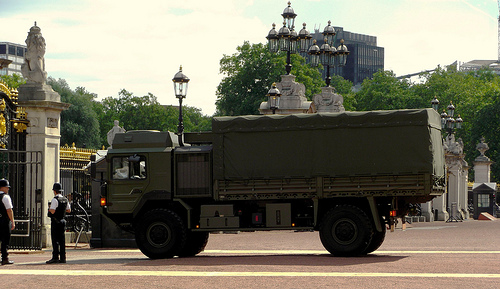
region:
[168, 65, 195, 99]
black metal street light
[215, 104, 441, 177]
green cover on back of truck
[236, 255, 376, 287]
white line painted on street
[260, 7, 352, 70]
bunch of black street lights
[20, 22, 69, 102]
statue on top of stone pillar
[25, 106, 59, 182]
large grey stone pillar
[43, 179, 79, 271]
police officer in black and white uniform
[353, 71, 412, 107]
tree with green leaves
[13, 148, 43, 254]
black metal gate entrance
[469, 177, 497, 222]
small green guard shack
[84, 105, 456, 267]
parked green military truck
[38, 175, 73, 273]
soldier standing in uniform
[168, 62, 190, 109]
light on black post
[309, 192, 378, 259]
black tire on truck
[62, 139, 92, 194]
black and gold fence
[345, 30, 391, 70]
top of city building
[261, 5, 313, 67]
cluster of decorative lights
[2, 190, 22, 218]
short white sleeve on soldier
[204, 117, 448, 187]
green canvas on back of truck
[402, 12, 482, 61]
white cloud in daytime sky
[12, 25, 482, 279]
military vehicle on the road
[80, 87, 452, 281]
large green bullet proof vehicle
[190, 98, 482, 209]
back carrying compartment of a vehicle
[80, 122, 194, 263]
front driving area of a vehicle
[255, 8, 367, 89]
black lamp posts with many lights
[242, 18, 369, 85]
many lanterns on top of lamp post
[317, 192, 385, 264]
back wheel of truck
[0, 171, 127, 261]
police guard of gate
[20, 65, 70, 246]
large pillar of wall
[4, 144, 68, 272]
black metal gate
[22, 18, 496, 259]
large green military vehicle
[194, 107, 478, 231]
back carrying compartment of vehicle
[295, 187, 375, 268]
back wheel of vehicle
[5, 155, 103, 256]
police guards by gate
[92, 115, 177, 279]
front driving area of vehicle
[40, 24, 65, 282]
front pillar for gate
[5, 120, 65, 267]
metal gate structure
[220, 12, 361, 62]
many lanterns on the end of a lampost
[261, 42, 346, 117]
black lamp post holding up lanters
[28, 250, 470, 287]
white lines drawn out on road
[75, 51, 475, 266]
a green army truck near a statue.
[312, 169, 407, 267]
the back left tire.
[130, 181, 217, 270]
the left tire of a truck.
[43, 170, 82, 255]
a man standing in front of a truck.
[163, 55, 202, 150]
a parking light.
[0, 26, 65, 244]
a tall fence pillar.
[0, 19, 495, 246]
pillars in a park.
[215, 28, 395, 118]
a forest filled with trees.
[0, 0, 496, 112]
a cloud filled blue sky.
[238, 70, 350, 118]
a very tall pillar.